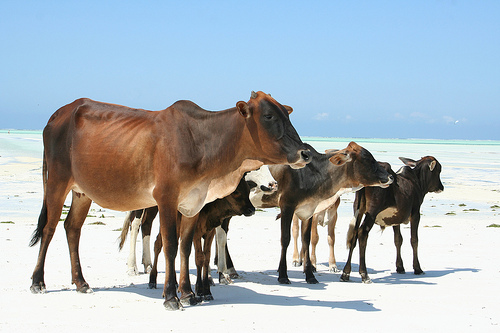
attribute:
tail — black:
[12, 154, 62, 248]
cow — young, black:
[347, 137, 435, 281]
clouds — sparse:
[324, 105, 430, 128]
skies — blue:
[148, 36, 269, 63]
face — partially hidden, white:
[234, 163, 287, 214]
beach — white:
[49, 243, 159, 286]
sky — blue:
[259, 19, 347, 79]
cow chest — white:
[181, 169, 221, 212]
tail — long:
[29, 148, 51, 258]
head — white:
[244, 163, 274, 199]